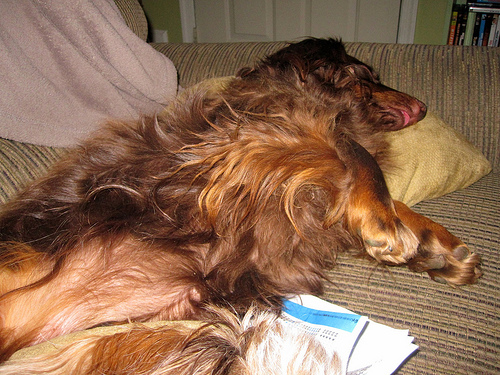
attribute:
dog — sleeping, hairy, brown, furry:
[10, 22, 489, 370]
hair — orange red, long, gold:
[247, 77, 291, 114]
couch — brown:
[409, 56, 469, 90]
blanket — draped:
[64, 37, 121, 80]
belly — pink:
[120, 273, 204, 301]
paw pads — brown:
[421, 251, 444, 271]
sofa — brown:
[168, 46, 225, 68]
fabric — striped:
[129, 9, 142, 22]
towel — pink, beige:
[16, 10, 120, 113]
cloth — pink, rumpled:
[13, 40, 44, 86]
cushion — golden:
[426, 125, 458, 146]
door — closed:
[181, 3, 401, 38]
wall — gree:
[154, 4, 182, 23]